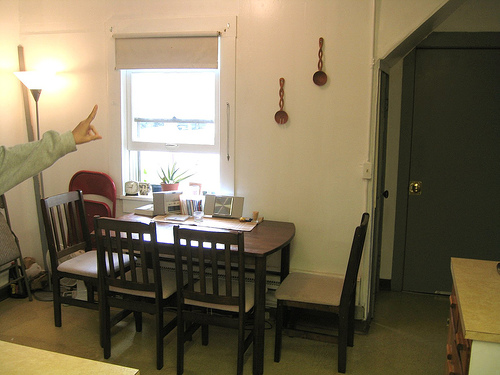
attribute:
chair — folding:
[70, 171, 114, 232]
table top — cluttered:
[150, 199, 265, 253]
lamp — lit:
[14, 68, 57, 289]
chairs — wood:
[73, 206, 271, 328]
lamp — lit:
[17, 69, 64, 298]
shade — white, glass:
[119, 20, 238, 81]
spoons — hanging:
[262, 36, 334, 128]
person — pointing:
[14, 114, 102, 163]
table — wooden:
[93, 202, 291, 364]